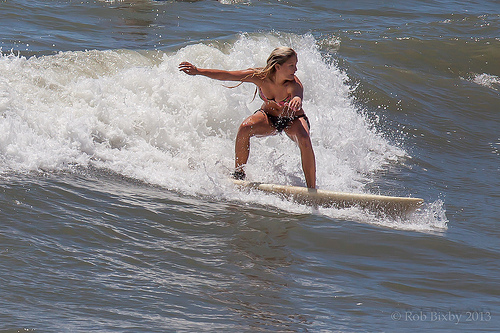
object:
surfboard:
[171, 157, 453, 234]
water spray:
[1, 79, 189, 142]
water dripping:
[276, 99, 304, 163]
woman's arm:
[171, 54, 266, 100]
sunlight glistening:
[297, 103, 322, 145]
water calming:
[0, 168, 494, 263]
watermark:
[381, 299, 500, 332]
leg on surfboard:
[281, 115, 324, 194]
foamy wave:
[0, 27, 408, 212]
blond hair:
[217, 43, 300, 105]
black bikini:
[251, 107, 314, 133]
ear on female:
[274, 63, 282, 73]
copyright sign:
[383, 292, 497, 331]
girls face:
[273, 53, 303, 81]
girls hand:
[173, 59, 202, 79]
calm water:
[2, 0, 500, 331]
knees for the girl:
[234, 120, 258, 138]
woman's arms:
[283, 73, 310, 112]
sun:
[82, 20, 272, 64]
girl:
[173, 36, 352, 207]